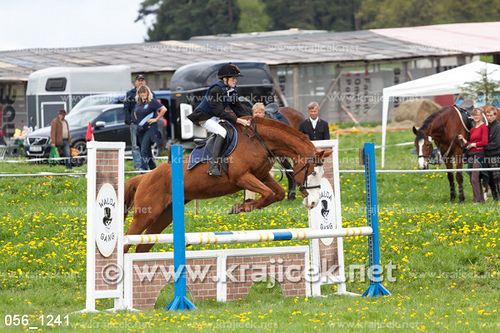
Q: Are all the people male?
A: No, they are both male and female.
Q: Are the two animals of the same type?
A: Yes, all the animals are horses.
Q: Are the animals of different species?
A: No, all the animals are horses.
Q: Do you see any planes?
A: No, there are no planes.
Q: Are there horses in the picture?
A: Yes, there is a horse.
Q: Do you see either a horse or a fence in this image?
A: Yes, there is a horse.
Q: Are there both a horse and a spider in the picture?
A: No, there is a horse but no spiders.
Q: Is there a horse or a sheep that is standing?
A: Yes, the horse is standing.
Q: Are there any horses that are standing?
A: Yes, there is a horse that is standing.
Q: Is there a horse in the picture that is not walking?
A: Yes, there is a horse that is standing.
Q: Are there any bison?
A: No, there are no bison.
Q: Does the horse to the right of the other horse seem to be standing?
A: Yes, the horse is standing.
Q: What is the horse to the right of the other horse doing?
A: The horse is standing.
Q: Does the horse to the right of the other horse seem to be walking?
A: No, the horse is standing.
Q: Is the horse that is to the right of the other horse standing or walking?
A: The horse is standing.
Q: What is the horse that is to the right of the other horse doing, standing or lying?
A: The horse is standing.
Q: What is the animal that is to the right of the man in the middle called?
A: The animal is a horse.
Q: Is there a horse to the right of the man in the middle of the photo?
A: Yes, there is a horse to the right of the man.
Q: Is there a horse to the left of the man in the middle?
A: No, the horse is to the right of the man.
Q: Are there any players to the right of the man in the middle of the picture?
A: No, there is a horse to the right of the man.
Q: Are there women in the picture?
A: Yes, there is a woman.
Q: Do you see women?
A: Yes, there is a woman.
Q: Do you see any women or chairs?
A: Yes, there is a woman.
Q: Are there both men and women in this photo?
A: Yes, there are both a woman and a man.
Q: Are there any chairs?
A: No, there are no chairs.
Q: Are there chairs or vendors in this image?
A: No, there are no chairs or vendors.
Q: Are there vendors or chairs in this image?
A: No, there are no chairs or vendors.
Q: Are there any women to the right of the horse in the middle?
A: Yes, there is a woman to the right of the horse.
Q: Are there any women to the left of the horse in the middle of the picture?
A: No, the woman is to the right of the horse.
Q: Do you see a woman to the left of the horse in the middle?
A: No, the woman is to the right of the horse.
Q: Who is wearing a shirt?
A: The woman is wearing a shirt.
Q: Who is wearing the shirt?
A: The woman is wearing a shirt.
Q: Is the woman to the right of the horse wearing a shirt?
A: Yes, the woman is wearing a shirt.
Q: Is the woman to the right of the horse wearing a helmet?
A: No, the woman is wearing a shirt.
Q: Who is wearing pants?
A: The woman is wearing pants.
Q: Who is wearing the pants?
A: The woman is wearing pants.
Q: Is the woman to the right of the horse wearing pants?
A: Yes, the woman is wearing pants.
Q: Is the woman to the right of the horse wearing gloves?
A: No, the woman is wearing pants.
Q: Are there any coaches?
A: No, there are no coaches.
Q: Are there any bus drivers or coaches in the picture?
A: No, there are no coaches or bus drivers.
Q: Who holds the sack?
A: The man holds the sack.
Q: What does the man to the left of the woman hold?
A: The man holds the sack.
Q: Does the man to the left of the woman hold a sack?
A: Yes, the man holds a sack.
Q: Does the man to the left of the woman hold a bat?
A: No, the man holds a sack.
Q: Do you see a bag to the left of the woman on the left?
A: No, there is a man to the left of the woman.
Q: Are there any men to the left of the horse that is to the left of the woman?
A: Yes, there is a man to the left of the horse.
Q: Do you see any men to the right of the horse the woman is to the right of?
A: No, the man is to the left of the horse.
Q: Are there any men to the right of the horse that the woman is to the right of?
A: No, the man is to the left of the horse.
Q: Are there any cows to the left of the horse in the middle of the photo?
A: No, there is a man to the left of the horse.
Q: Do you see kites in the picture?
A: No, there are no kites.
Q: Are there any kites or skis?
A: No, there are no kites or skis.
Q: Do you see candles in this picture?
A: No, there are no candles.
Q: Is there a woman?
A: Yes, there is a woman.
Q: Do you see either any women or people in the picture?
A: Yes, there is a woman.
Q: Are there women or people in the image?
A: Yes, there is a woman.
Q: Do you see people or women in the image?
A: Yes, there is a woman.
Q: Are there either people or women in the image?
A: Yes, there is a woman.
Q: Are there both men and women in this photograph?
A: Yes, there are both a woman and a man.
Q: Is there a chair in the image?
A: No, there are no chairs.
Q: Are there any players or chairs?
A: No, there are no chairs or players.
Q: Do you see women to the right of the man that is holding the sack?
A: Yes, there is a woman to the right of the man.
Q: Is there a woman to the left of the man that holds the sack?
A: No, the woman is to the right of the man.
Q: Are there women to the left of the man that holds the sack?
A: No, the woman is to the right of the man.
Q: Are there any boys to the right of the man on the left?
A: No, there is a woman to the right of the man.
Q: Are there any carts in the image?
A: No, there are no carts.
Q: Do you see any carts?
A: No, there are no carts.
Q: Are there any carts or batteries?
A: No, there are no carts or batteries.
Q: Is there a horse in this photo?
A: Yes, there is a horse.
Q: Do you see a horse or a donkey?
A: Yes, there is a horse.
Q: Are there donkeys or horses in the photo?
A: Yes, there is a horse.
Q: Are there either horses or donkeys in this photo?
A: Yes, there is a horse.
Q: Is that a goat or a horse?
A: That is a horse.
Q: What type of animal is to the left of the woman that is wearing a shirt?
A: The animal is a horse.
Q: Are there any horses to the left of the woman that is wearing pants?
A: Yes, there is a horse to the left of the woman.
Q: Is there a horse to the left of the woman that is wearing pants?
A: Yes, there is a horse to the left of the woman.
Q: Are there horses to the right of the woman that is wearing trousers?
A: No, the horse is to the left of the woman.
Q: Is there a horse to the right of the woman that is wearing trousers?
A: No, the horse is to the left of the woman.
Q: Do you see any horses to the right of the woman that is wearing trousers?
A: No, the horse is to the left of the woman.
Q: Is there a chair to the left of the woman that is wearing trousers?
A: No, there is a horse to the left of the woman.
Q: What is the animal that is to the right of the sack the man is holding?
A: The animal is a horse.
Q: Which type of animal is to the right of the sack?
A: The animal is a horse.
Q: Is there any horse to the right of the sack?
A: Yes, there is a horse to the right of the sack.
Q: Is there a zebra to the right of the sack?
A: No, there is a horse to the right of the sack.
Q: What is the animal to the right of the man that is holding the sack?
A: The animal is a horse.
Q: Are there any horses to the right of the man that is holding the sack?
A: Yes, there is a horse to the right of the man.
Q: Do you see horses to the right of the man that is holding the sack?
A: Yes, there is a horse to the right of the man.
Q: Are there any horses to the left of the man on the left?
A: No, the horse is to the right of the man.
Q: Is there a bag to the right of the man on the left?
A: No, there is a horse to the right of the man.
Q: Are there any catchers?
A: No, there are no catchers.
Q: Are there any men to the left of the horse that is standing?
A: Yes, there is a man to the left of the horse.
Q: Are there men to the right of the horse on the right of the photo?
A: No, the man is to the left of the horse.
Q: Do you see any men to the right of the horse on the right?
A: No, the man is to the left of the horse.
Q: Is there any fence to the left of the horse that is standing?
A: No, there is a man to the left of the horse.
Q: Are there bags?
A: No, there are no bags.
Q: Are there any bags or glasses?
A: No, there are no bags or glasses.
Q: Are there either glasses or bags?
A: No, there are no bags or glasses.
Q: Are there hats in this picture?
A: Yes, there is a hat.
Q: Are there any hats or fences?
A: Yes, there is a hat.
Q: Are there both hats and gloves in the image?
A: No, there is a hat but no gloves.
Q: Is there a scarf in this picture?
A: No, there are no scarves.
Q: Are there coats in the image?
A: Yes, there is a coat.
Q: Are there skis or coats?
A: Yes, there is a coat.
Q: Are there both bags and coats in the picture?
A: No, there is a coat but no bags.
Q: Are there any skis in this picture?
A: No, there are no skis.